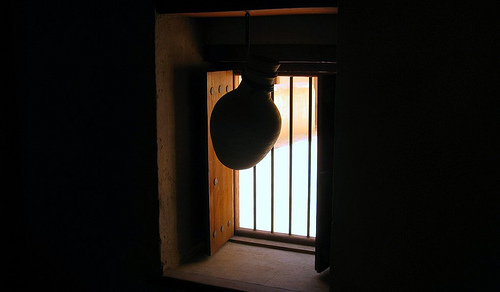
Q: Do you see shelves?
A: No, there are no shelves.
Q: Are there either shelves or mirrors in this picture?
A: No, there are no shelves or mirrors.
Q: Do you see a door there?
A: Yes, there is a door.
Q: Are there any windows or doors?
A: Yes, there is a door.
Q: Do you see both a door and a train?
A: No, there is a door but no trains.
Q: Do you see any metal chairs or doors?
A: Yes, there is a metal door.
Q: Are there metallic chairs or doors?
A: Yes, there is a metal door.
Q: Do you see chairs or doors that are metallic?
A: Yes, the door is metallic.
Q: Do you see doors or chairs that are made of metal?
A: Yes, the door is made of metal.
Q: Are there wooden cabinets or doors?
A: Yes, there is a wood door.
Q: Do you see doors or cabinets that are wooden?
A: Yes, the door is wooden.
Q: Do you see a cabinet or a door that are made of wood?
A: Yes, the door is made of wood.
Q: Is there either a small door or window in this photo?
A: Yes, there is a small door.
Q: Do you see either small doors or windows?
A: Yes, there is a small door.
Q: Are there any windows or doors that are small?
A: Yes, the door is small.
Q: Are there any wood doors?
A: Yes, there is a wood door.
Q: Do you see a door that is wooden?
A: Yes, there is a door that is wooden.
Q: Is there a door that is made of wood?
A: Yes, there is a door that is made of wood.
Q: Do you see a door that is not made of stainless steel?
A: Yes, there is a door that is made of wood.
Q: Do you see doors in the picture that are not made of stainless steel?
A: Yes, there is a door that is made of wood.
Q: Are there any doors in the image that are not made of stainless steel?
A: Yes, there is a door that is made of wood.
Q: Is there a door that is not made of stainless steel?
A: Yes, there is a door that is made of wood.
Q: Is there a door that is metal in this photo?
A: Yes, there is a metal door.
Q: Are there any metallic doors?
A: Yes, there is a metal door.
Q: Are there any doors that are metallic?
A: Yes, there is a door that is metallic.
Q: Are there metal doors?
A: Yes, there is a door that is made of metal.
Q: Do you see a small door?
A: Yes, there is a small door.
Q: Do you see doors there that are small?
A: Yes, there is a door that is small.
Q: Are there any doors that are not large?
A: Yes, there is a small door.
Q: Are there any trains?
A: No, there are no trains.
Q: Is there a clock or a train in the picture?
A: No, there are no trains or clocks.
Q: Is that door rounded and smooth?
A: Yes, the door is rounded and smooth.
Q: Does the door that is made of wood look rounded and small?
A: Yes, the door is rounded and small.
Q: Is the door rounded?
A: Yes, the door is rounded.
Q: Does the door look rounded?
A: Yes, the door is rounded.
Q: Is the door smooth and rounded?
A: Yes, the door is smooth and rounded.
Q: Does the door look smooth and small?
A: Yes, the door is smooth and small.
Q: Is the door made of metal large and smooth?
A: No, the door is smooth but small.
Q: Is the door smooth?
A: Yes, the door is smooth.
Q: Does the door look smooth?
A: Yes, the door is smooth.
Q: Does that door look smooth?
A: Yes, the door is smooth.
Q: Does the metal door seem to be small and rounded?
A: Yes, the door is small and rounded.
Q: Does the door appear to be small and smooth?
A: Yes, the door is small and smooth.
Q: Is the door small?
A: Yes, the door is small.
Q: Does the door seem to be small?
A: Yes, the door is small.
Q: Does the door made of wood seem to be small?
A: Yes, the door is small.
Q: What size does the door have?
A: The door has small size.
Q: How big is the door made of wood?
A: The door is small.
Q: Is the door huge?
A: No, the door is small.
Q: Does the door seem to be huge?
A: No, the door is small.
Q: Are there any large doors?
A: No, there is a door but it is small.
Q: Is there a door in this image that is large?
A: No, there is a door but it is small.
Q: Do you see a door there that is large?
A: No, there is a door but it is small.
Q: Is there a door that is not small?
A: No, there is a door but it is small.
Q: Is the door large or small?
A: The door is small.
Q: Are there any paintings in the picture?
A: No, there are no paintings.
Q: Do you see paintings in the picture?
A: No, there are no paintings.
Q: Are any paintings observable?
A: No, there are no paintings.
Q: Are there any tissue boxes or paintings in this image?
A: No, there are no paintings or tissue boxes.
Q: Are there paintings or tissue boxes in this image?
A: No, there are no paintings or tissue boxes.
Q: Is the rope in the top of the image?
A: Yes, the rope is in the top of the image.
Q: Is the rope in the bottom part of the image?
A: No, the rope is in the top of the image.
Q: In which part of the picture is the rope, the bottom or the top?
A: The rope is in the top of the image.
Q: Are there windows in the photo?
A: Yes, there is a window.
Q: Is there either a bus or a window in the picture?
A: Yes, there is a window.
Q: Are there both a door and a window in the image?
A: Yes, there are both a window and a door.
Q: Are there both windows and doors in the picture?
A: Yes, there are both a window and a door.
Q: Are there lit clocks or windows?
A: Yes, there is a lit window.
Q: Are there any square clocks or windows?
A: Yes, there is a square window.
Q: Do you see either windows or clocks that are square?
A: Yes, the window is square.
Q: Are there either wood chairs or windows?
A: Yes, there is a wood window.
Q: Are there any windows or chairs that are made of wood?
A: Yes, the window is made of wood.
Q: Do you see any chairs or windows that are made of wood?
A: Yes, the window is made of wood.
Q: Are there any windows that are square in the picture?
A: Yes, there is a square window.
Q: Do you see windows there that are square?
A: Yes, there is a window that is square.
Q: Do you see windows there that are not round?
A: Yes, there is a square window.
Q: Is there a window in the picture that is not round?
A: Yes, there is a square window.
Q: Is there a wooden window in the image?
A: Yes, there is a wood window.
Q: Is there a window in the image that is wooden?
A: Yes, there is a window that is wooden.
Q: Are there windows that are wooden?
A: Yes, there is a window that is wooden.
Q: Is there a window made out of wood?
A: Yes, there is a window that is made of wood.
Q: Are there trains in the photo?
A: No, there are no trains.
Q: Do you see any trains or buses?
A: No, there are no trains or buses.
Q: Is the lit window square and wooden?
A: Yes, the window is square and wooden.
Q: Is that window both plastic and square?
A: No, the window is square but wooden.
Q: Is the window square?
A: Yes, the window is square.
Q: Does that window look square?
A: Yes, the window is square.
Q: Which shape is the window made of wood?
A: The window is square.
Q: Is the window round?
A: No, the window is square.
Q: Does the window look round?
A: No, the window is square.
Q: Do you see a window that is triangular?
A: No, there is a window but it is square.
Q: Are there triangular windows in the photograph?
A: No, there is a window but it is square.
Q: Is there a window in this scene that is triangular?
A: No, there is a window but it is square.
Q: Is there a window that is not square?
A: No, there is a window but it is square.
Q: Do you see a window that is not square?
A: No, there is a window but it is square.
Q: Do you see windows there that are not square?
A: No, there is a window but it is square.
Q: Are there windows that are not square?
A: No, there is a window but it is square.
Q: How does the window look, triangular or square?
A: The window is square.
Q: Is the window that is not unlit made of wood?
A: Yes, the window is made of wood.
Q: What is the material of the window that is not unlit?
A: The window is made of wood.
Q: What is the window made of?
A: The window is made of wood.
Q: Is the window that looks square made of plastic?
A: No, the window is made of wood.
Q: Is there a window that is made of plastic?
A: No, there is a window but it is made of wood.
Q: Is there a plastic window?
A: No, there is a window but it is made of wood.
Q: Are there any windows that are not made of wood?
A: No, there is a window but it is made of wood.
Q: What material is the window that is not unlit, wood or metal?
A: The window is made of wood.